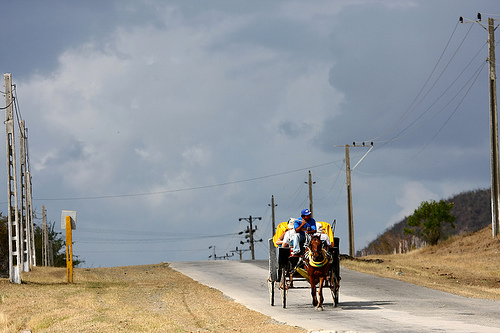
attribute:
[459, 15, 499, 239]
pole — telephone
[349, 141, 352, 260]
pole — telephone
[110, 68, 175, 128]
clouds — white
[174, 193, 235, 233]
clouds sky — white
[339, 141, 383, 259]
pole — telephone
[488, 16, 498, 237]
pole — telephone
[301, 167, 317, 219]
pole — telephone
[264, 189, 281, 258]
pole — telephone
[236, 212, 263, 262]
pole — telephone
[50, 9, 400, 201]
clouds — white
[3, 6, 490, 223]
sky — blue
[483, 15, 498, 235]
pole — telephone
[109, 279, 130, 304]
grass — brown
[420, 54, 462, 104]
cloud — white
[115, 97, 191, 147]
clouds — white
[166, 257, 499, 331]
road — grey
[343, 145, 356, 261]
post — wooden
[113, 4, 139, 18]
cloud — white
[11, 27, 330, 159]
cloud — white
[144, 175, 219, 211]
cloud — white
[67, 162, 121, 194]
cloud — white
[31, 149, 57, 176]
cloud — white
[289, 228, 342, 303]
horse — brown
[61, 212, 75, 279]
sign post — yellow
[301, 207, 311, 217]
hat — blue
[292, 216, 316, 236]
shirt — blue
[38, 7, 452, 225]
clouds — white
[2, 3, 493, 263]
clouds — white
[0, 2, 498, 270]
sky — blue